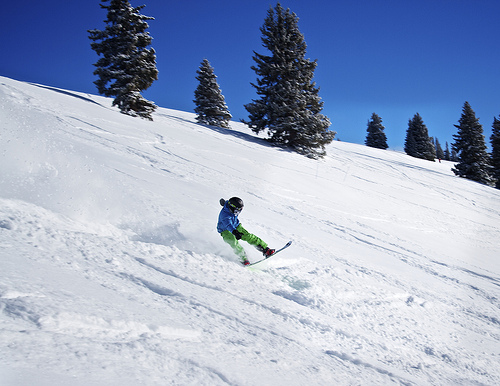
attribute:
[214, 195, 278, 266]
person — snowboarding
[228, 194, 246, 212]
helmet — black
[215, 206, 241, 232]
jacket — blue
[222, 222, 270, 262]
pants — green, bright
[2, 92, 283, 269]
snow — tossed, flying, flurry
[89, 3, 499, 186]
trees — covered, many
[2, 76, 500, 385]
snow — white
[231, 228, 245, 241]
gloves — black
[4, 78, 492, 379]
ground — covered, sloppy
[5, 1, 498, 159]
sky — clear, cloudless, blue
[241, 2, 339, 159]
tree — large, green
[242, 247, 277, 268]
boots — red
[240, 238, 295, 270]
snowboard — tracking